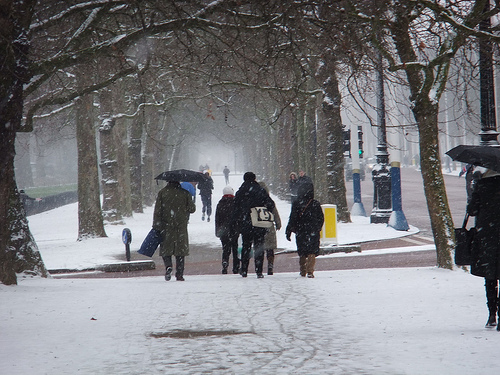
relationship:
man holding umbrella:
[149, 177, 195, 282] [148, 166, 213, 182]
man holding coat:
[149, 177, 195, 282] [151, 186, 193, 256]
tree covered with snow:
[388, 1, 498, 271] [29, 31, 495, 113]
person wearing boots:
[283, 177, 327, 278] [294, 236, 338, 301]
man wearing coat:
[152, 177, 196, 280] [152, 180, 196, 256]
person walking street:
[448, 142, 498, 332] [347, 160, 476, 265]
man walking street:
[152, 177, 196, 280] [347, 160, 476, 265]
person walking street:
[234, 162, 275, 273] [347, 160, 476, 265]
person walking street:
[212, 186, 242, 272] [347, 160, 476, 265]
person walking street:
[283, 182, 326, 277] [347, 160, 476, 265]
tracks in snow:
[144, 275, 364, 374] [0, 171, 498, 373]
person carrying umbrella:
[464, 144, 500, 331] [444, 142, 484, 171]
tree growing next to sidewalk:
[388, 1, 498, 271] [46, 233, 435, 278]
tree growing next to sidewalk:
[75, 1, 107, 241] [46, 233, 435, 278]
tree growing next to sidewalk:
[326, 3, 350, 222] [46, 233, 435, 278]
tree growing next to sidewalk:
[284, 3, 400, 222] [46, 233, 435, 278]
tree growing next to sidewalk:
[15, 1, 152, 242] [46, 233, 435, 278]